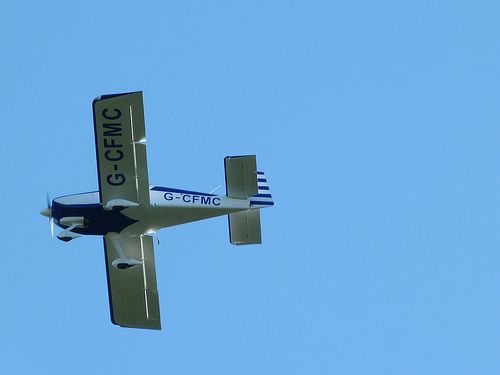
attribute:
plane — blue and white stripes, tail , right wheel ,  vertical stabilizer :
[32, 83, 277, 333]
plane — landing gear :
[46, 123, 301, 268]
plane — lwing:
[77, 82, 171, 350]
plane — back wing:
[220, 141, 281, 244]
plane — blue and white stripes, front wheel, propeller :
[53, 83, 268, 341]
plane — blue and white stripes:
[64, 81, 309, 341]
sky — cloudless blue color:
[315, 40, 472, 207]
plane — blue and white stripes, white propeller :
[35, 83, 307, 324]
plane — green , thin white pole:
[40, 82, 320, 340]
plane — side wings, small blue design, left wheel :
[42, 73, 289, 346]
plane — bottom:
[131, 185, 263, 219]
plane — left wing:
[56, 96, 284, 336]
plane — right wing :
[95, 227, 175, 324]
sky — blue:
[1, 0, 496, 371]